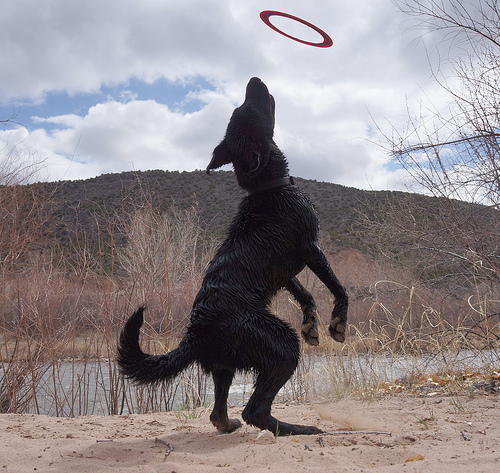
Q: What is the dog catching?
A: Frisbee.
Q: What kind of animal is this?
A: Dog.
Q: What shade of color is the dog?
A: Black.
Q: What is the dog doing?
A: Catching a frisbee.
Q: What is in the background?
A: Mountain.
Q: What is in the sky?
A: Clouds.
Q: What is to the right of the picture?
A: Tree branches.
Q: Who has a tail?
A: The dog.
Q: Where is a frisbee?
A: In the air.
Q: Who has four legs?
A: A dog.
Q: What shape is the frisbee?
A: Round.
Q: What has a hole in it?
A: A frisbee.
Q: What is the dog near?
A: Water.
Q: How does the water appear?
A: Calm.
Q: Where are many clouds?
A: In the sky.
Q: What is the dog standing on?
A: Sand.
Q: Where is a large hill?
A: Across the water.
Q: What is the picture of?
A: A black dog trying to catch a red ring.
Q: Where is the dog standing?
A: On brown sandy soil.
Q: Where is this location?
A: On a river bank.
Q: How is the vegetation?
A: Brown and dry.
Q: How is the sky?
A: Blue sky full of lots of white clouds.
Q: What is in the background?
A: A hill with green trees.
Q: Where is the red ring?
A: In air above the dog.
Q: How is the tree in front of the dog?
A: Leafless and dry.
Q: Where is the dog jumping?
A: In the sand.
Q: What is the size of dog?
A: Tall black dog.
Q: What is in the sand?
A: Swamp grass.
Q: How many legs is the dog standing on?
A: Two.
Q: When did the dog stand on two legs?
A: When the frisbee was thrown.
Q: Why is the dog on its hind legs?
A: To reach the frisbee.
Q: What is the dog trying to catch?
A: A frisbee.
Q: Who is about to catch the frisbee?
A: A dog.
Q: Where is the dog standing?
A: On sand.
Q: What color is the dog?
A: Black.